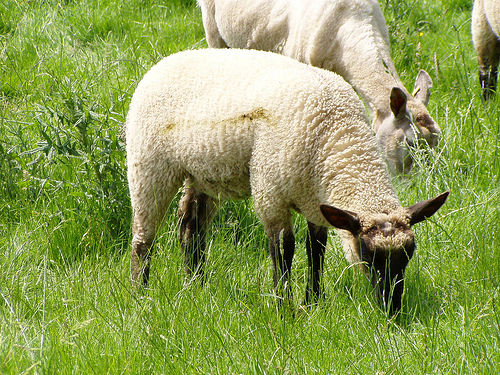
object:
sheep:
[123, 48, 450, 320]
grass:
[1, 1, 499, 370]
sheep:
[199, 0, 442, 180]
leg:
[127, 162, 182, 291]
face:
[363, 245, 413, 311]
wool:
[125, 48, 415, 264]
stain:
[163, 107, 275, 133]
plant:
[34, 72, 123, 236]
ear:
[319, 203, 359, 235]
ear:
[406, 190, 449, 226]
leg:
[305, 215, 328, 308]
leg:
[179, 178, 231, 286]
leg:
[253, 189, 294, 318]